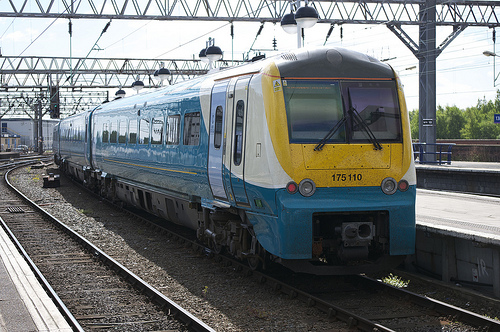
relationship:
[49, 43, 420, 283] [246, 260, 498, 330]
passenger train on railway track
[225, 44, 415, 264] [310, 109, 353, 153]
cabin with wiper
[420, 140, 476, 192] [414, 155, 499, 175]
railway in platform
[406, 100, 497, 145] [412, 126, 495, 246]
trees on side of platform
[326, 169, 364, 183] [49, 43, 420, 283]
175110 on passenger train